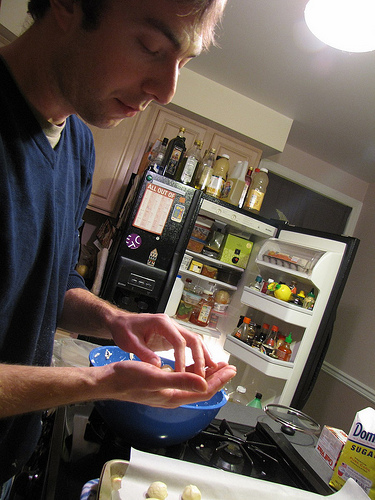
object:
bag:
[328, 405, 375, 500]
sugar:
[327, 403, 375, 498]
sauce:
[275, 343, 290, 362]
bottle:
[274, 332, 294, 362]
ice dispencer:
[110, 254, 168, 311]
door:
[220, 222, 361, 417]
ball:
[145, 480, 169, 500]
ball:
[271, 282, 294, 303]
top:
[267, 277, 275, 283]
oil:
[218, 177, 245, 210]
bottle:
[217, 158, 250, 207]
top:
[236, 159, 243, 166]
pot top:
[262, 402, 321, 439]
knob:
[280, 423, 296, 437]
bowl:
[88, 340, 229, 446]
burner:
[82, 406, 188, 461]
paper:
[118, 443, 374, 499]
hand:
[109, 359, 236, 411]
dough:
[157, 365, 174, 392]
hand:
[110, 308, 219, 380]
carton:
[260, 249, 319, 275]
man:
[2, 0, 238, 498]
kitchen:
[0, 0, 375, 499]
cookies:
[146, 478, 168, 499]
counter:
[214, 397, 339, 500]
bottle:
[242, 164, 270, 216]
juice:
[242, 172, 269, 214]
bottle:
[234, 314, 251, 345]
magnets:
[132, 181, 177, 236]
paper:
[132, 183, 176, 237]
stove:
[63, 413, 336, 500]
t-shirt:
[0, 49, 98, 482]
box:
[314, 425, 353, 470]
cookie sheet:
[97, 458, 138, 500]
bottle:
[192, 146, 216, 192]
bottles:
[175, 139, 201, 188]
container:
[303, 290, 316, 310]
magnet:
[124, 231, 142, 252]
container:
[204, 152, 230, 198]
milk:
[164, 275, 185, 318]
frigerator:
[75, 169, 361, 424]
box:
[215, 232, 254, 272]